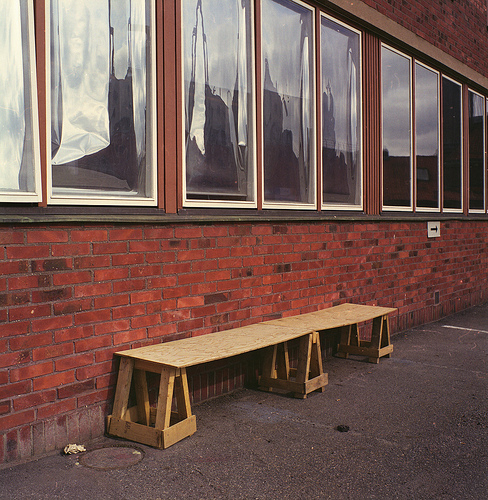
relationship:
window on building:
[43, 4, 170, 215] [16, 10, 483, 303]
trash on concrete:
[56, 437, 87, 457] [231, 419, 478, 498]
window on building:
[184, 1, 363, 212] [16, 10, 483, 303]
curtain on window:
[56, 11, 116, 164] [43, 4, 170, 215]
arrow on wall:
[427, 226, 440, 234] [59, 252, 232, 295]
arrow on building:
[427, 226, 440, 234] [16, 10, 483, 303]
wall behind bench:
[59, 252, 232, 295] [95, 282, 401, 433]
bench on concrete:
[95, 282, 401, 433] [231, 419, 478, 498]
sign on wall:
[422, 220, 445, 242] [59, 252, 232, 295]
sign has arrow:
[422, 220, 445, 242] [427, 226, 440, 234]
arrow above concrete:
[427, 226, 440, 234] [231, 419, 478, 498]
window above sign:
[380, 40, 466, 217] [422, 220, 445, 242]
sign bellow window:
[422, 220, 445, 242] [380, 40, 466, 217]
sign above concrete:
[422, 220, 445, 242] [231, 419, 478, 498]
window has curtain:
[43, 4, 170, 215] [56, 11, 116, 164]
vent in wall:
[430, 289, 443, 307] [59, 252, 232, 295]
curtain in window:
[196, 12, 249, 155] [184, 1, 363, 212]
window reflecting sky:
[380, 40, 466, 217] [389, 71, 410, 133]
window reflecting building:
[380, 40, 466, 217] [419, 156, 435, 205]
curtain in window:
[269, 36, 309, 154] [184, 1, 363, 212]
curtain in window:
[326, 65, 353, 161] [184, 1, 363, 212]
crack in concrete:
[406, 350, 477, 386] [231, 419, 478, 498]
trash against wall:
[56, 437, 87, 457] [59, 252, 232, 295]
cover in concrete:
[71, 443, 147, 479] [231, 419, 478, 498]